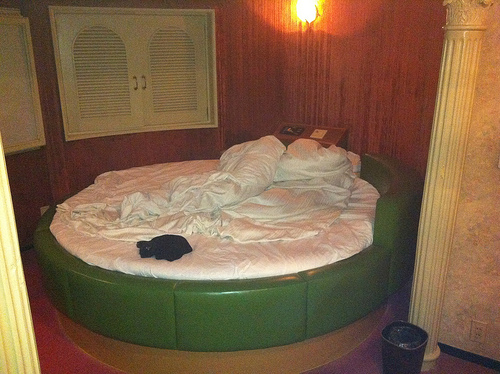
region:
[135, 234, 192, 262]
black adult cat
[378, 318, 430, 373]
black trash can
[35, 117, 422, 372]
green and brown round rotating bed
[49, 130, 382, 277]
white bottom and top sheets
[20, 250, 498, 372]
dark maroon carpet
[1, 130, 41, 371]
cream colored column on the left side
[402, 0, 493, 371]
cream colored column on the right side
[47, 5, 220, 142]
white window shutters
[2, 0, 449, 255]
brown wood paneled walls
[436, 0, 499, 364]
mottled beige wall paper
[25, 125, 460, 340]
this is a bed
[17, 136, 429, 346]
the bed is round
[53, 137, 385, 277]
this is a white sheet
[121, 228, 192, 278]
a black cloth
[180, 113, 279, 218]
a person sleeping on the bed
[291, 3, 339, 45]
this is a lamp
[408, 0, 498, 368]
this is a pillar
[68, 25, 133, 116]
this is a window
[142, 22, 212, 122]
this is a window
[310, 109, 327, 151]
a small notebook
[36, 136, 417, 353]
round rotaional green leather bed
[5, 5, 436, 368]
small wooden room with round bed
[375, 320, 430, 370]
trash cannext to room with bed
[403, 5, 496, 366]
Roman design pillar seperating room of bed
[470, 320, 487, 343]
wall socket on wall in outer room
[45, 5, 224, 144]
white shutter windows in room with bed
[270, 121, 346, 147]
rotational electic bed control device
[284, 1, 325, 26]
light over bed in room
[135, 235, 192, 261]
garment at foot of bed in room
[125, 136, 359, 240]
bundle of sheets on top of bed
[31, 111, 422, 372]
This is a bed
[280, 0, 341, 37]
This is a lamp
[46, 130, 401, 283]
These are bed sheets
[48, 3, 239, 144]
This is a side board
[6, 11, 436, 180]
This is a wall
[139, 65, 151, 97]
Handle of a side wall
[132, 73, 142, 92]
Handle of a side wall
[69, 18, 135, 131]
These are ventilations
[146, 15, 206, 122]
These are ventilations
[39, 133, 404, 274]
These are white bed sheets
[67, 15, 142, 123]
This is a mesh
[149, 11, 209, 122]
This is a mesh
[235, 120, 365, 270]
This is a mesh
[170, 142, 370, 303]
This is a bed sheet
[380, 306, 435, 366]
This is a pole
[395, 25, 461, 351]
This is a pole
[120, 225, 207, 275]
This is a cardigan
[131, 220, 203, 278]
This is a black cardigan